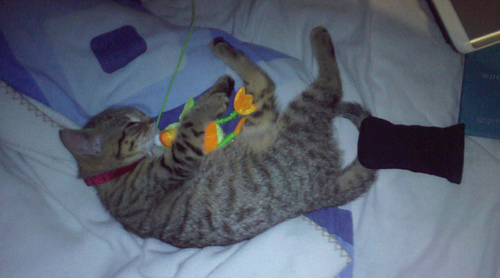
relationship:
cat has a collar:
[60, 26, 380, 247] [83, 155, 147, 186]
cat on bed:
[60, 26, 380, 247] [0, 0, 499, 277]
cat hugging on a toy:
[60, 26, 380, 247] [156, 1, 258, 157]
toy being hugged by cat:
[156, 1, 258, 157] [60, 26, 380, 247]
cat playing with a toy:
[60, 26, 380, 247] [156, 1, 258, 157]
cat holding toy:
[60, 26, 380, 247] [156, 1, 258, 157]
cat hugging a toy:
[60, 26, 380, 247] [156, 1, 258, 157]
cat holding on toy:
[60, 26, 380, 247] [156, 1, 258, 157]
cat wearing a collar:
[60, 26, 380, 247] [83, 155, 147, 186]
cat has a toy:
[60, 26, 380, 247] [156, 1, 258, 157]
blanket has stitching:
[0, 78, 351, 277] [0, 77, 353, 266]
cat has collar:
[60, 26, 380, 247] [83, 155, 147, 186]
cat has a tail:
[60, 26, 380, 247] [332, 100, 379, 206]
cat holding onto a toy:
[60, 26, 380, 247] [156, 1, 258, 157]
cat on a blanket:
[60, 26, 380, 247] [0, 78, 351, 277]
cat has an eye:
[60, 26, 380, 247] [123, 121, 139, 129]